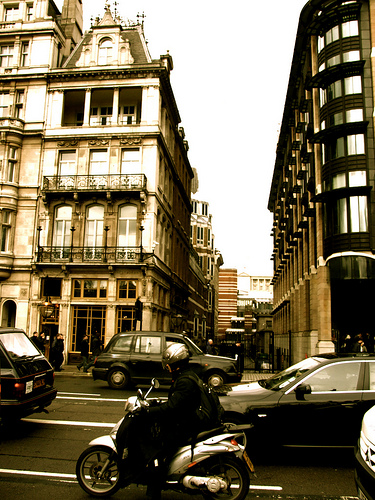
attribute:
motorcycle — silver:
[72, 373, 254, 492]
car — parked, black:
[86, 327, 245, 391]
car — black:
[205, 346, 359, 453]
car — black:
[5, 325, 58, 429]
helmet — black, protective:
[160, 339, 189, 368]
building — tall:
[266, 6, 362, 372]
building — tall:
[32, 0, 177, 368]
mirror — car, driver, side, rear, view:
[293, 381, 312, 396]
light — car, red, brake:
[12, 379, 22, 391]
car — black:
[213, 350, 352, 466]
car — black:
[4, 326, 55, 441]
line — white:
[0, 465, 282, 498]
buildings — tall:
[215, 268, 274, 338]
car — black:
[217, 351, 374, 454]